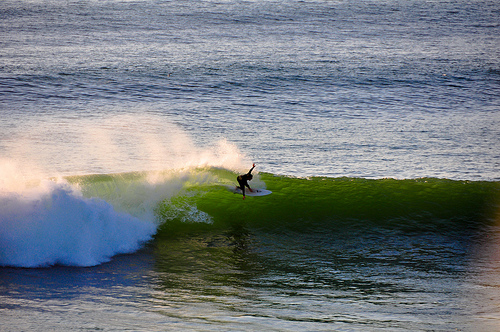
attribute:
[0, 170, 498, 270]
wave — large, white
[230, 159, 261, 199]
person — surfing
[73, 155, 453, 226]
water — green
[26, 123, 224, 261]
waves — white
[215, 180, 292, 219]
board — white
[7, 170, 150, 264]
water — white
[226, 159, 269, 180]
person — surfing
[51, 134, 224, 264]
water — splash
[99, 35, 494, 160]
water — blue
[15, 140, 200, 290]
water — white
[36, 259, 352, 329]
water — dark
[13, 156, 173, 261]
wave — large, curling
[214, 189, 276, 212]
surfboard — white, pointy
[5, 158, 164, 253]
wave — white, crashing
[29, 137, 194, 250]
wave — misty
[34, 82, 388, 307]
waters — calm, blue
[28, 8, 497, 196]
waters — blue, calm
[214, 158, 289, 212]
surfboarder — riding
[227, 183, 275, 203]
surfboard — black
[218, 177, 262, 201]
surfboard — black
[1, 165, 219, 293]
wave — large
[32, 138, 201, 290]
wave — white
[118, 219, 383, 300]
water — green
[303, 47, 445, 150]
water — calm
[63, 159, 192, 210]
wave — small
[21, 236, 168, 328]
water — calm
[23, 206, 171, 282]
water — green